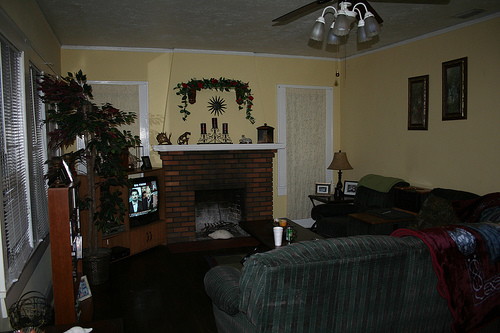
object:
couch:
[203, 186, 499, 332]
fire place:
[153, 143, 274, 239]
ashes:
[209, 230, 234, 240]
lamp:
[328, 149, 354, 199]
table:
[308, 194, 355, 206]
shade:
[326, 149, 353, 171]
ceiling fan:
[272, 0, 385, 51]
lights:
[307, 15, 327, 49]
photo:
[318, 185, 327, 193]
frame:
[314, 182, 331, 197]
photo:
[347, 183, 357, 193]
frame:
[343, 180, 359, 197]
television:
[128, 176, 160, 227]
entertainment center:
[78, 168, 165, 259]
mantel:
[151, 143, 284, 152]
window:
[0, 37, 51, 293]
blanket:
[387, 225, 498, 332]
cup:
[273, 227, 284, 246]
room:
[1, 0, 499, 332]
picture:
[440, 55, 467, 121]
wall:
[339, 13, 499, 196]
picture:
[408, 75, 428, 130]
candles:
[196, 122, 210, 143]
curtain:
[286, 87, 327, 220]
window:
[275, 82, 335, 217]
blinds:
[1, 43, 38, 270]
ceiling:
[36, 1, 499, 58]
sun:
[207, 95, 228, 116]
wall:
[169, 50, 265, 143]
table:
[238, 218, 325, 251]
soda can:
[286, 226, 292, 241]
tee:
[36, 69, 144, 286]